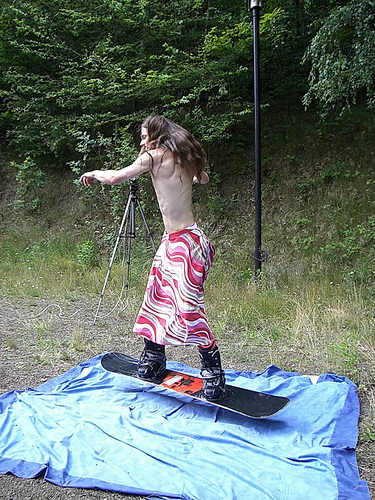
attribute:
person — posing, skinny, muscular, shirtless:
[77, 113, 226, 397]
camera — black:
[93, 177, 157, 325]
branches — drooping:
[297, 1, 372, 135]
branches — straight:
[0, 1, 295, 166]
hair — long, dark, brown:
[141, 112, 211, 184]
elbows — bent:
[105, 168, 209, 184]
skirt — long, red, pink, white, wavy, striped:
[130, 223, 218, 348]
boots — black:
[134, 338, 229, 401]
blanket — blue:
[3, 353, 370, 498]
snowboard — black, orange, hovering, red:
[100, 351, 290, 419]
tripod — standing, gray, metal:
[90, 197, 159, 325]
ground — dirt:
[0, 123, 374, 497]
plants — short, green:
[1, 130, 374, 270]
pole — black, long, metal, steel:
[249, 0, 263, 288]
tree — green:
[3, 1, 285, 178]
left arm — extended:
[76, 151, 154, 189]